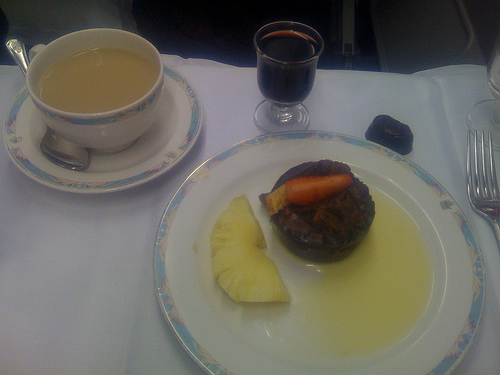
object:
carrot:
[286, 175, 350, 205]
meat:
[260, 159, 376, 261]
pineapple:
[208, 195, 294, 304]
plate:
[150, 130, 483, 374]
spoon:
[5, 38, 90, 171]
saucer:
[0, 63, 200, 196]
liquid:
[258, 30, 319, 101]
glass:
[253, 21, 323, 133]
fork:
[465, 130, 499, 248]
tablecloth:
[1, 55, 498, 375]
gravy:
[39, 49, 159, 114]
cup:
[24, 28, 166, 155]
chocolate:
[365, 114, 414, 155]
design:
[153, 127, 484, 374]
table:
[0, 53, 499, 374]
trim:
[5, 64, 202, 192]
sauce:
[285, 193, 433, 356]